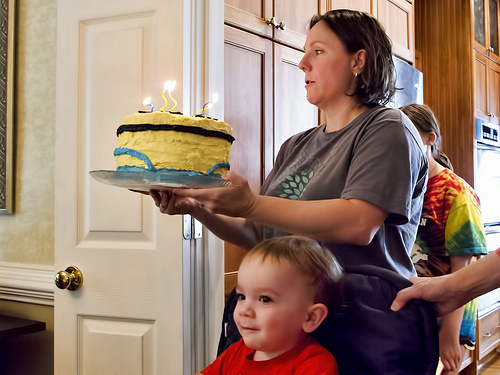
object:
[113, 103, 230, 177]
icing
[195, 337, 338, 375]
shirt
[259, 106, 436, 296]
shirt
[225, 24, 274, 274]
door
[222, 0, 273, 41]
cabinet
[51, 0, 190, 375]
door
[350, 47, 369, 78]
ear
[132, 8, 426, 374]
woman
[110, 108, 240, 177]
cake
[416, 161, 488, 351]
shirt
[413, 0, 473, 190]
cabinets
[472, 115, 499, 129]
over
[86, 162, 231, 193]
plate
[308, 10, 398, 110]
hair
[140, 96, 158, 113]
candles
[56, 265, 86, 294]
knob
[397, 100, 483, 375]
people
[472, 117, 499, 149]
oven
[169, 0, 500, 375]
kitchen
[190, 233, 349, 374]
baby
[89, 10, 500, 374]
birthday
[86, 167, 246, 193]
pan